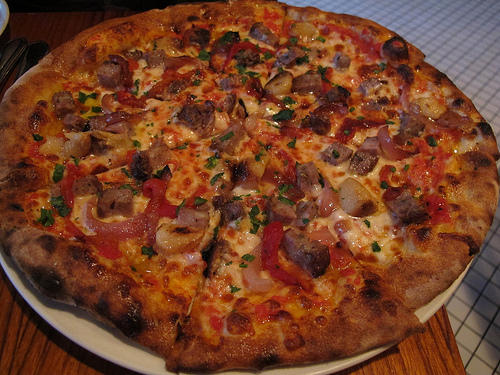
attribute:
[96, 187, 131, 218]
sausage piece — small, brown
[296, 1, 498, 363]
tiles — black, white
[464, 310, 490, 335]
tiles — white, square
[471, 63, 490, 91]
tiles — white, square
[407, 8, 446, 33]
tiles — white, square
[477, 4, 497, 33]
tiles — white, square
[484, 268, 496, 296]
tiles — white, square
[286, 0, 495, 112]
tile — white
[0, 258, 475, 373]
plate — white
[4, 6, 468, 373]
table — wooden, small, brown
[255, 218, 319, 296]
sauce — small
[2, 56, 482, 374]
plate — white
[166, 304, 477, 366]
crust — brown, black, burnt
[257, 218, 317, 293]
pepper — red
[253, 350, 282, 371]
burnt crust — small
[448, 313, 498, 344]
tiles — square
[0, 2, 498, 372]
pizza — large, round, multi-topping, cooked, delicious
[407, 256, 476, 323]
plate — white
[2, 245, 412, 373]
plate — white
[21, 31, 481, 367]
plate — white 